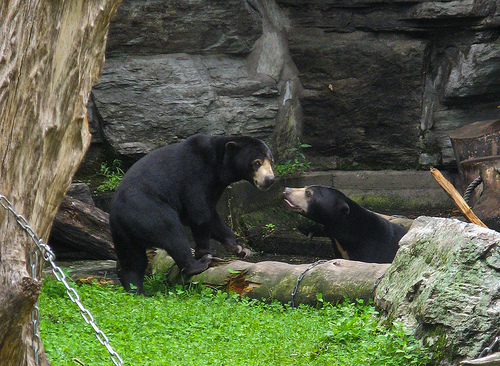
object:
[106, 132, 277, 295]
bear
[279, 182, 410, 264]
bear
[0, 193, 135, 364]
chain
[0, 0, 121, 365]
tree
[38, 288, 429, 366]
foliage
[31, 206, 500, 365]
ground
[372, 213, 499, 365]
boulder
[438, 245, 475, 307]
moss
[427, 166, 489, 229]
stick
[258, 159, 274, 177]
tan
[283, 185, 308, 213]
tan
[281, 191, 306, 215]
mouth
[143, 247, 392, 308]
log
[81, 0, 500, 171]
wall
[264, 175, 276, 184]
nose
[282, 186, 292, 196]
nose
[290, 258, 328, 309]
chain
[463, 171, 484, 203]
rope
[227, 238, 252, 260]
paw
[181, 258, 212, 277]
foot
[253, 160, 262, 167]
eye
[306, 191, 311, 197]
eye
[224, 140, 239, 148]
ear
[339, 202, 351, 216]
ear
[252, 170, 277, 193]
snout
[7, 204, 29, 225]
metal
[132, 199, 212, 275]
leg